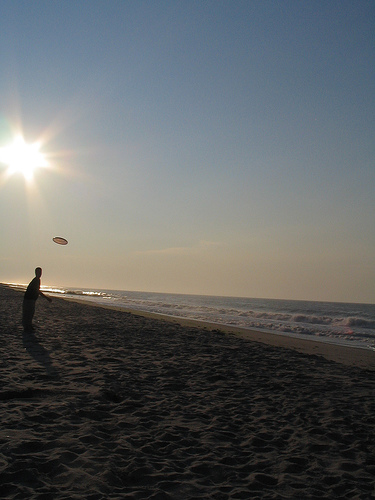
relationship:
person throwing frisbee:
[21, 266, 53, 329] [52, 236, 68, 246]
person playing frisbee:
[21, 266, 53, 329] [52, 236, 68, 246]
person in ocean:
[21, 266, 53, 329] [0, 281, 375, 318]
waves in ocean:
[132, 303, 374, 339] [3, 280, 374, 352]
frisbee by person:
[52, 236, 68, 246] [18, 264, 54, 329]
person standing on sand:
[21, 266, 53, 329] [0, 281, 375, 499]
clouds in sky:
[0, 225, 373, 302] [2, 1, 374, 303]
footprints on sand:
[2, 347, 309, 498] [2, 287, 373, 499]